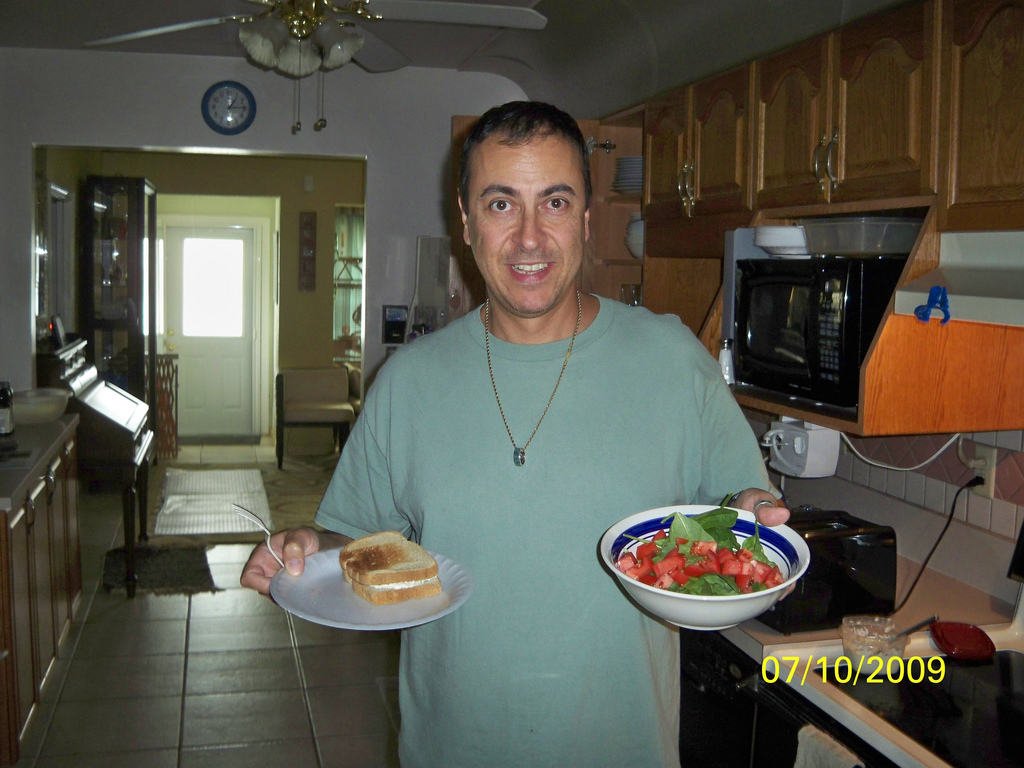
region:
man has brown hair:
[440, 109, 602, 224]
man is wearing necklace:
[469, 309, 583, 450]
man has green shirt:
[265, 331, 744, 762]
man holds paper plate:
[247, 533, 503, 682]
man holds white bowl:
[594, 485, 798, 635]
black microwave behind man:
[703, 214, 915, 436]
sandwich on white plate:
[291, 558, 478, 619]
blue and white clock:
[210, 78, 258, 118]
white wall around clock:
[159, 72, 319, 140]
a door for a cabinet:
[626, 103, 684, 190]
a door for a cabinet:
[751, 51, 819, 197]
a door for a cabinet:
[845, 22, 925, 197]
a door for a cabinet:
[934, 13, 1015, 204]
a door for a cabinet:
[0, 519, 48, 717]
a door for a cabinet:
[25, 468, 61, 700]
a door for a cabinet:
[39, 446, 79, 659]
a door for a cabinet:
[59, 440, 101, 625]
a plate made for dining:
[265, 519, 469, 650]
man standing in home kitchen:
[239, 97, 791, 766]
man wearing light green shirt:
[236, 102, 793, 766]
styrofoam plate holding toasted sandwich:
[266, 530, 472, 629]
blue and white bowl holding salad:
[598, 502, 813, 632]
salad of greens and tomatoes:
[615, 506, 786, 596]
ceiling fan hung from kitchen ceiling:
[86, 0, 552, 138]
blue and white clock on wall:
[198, 76, 260, 134]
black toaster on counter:
[751, 505, 900, 638]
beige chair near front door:
[273, 361, 360, 472]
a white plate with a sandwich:
[264, 527, 462, 638]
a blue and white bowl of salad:
[592, 496, 815, 632]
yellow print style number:
[760, 656, 783, 686]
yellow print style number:
[774, 652, 803, 690]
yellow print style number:
[816, 650, 830, 693]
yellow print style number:
[888, 650, 907, 686]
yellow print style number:
[905, 644, 929, 692]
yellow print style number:
[923, 647, 947, 693]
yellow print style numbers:
[758, 649, 803, 692]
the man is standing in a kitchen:
[239, 99, 812, 766]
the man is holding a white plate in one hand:
[268, 532, 474, 640]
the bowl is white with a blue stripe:
[593, 504, 815, 638]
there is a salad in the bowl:
[612, 504, 787, 603]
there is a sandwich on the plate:
[340, 531, 443, 605]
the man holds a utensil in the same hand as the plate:
[238, 504, 290, 561]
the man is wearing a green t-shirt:
[315, 295, 775, 766]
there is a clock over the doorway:
[195, 80, 260, 132]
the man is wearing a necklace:
[481, 291, 586, 465]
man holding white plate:
[230, 103, 809, 764]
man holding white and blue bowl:
[238, 103, 808, 761]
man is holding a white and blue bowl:
[239, 100, 816, 767]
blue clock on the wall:
[0, 47, 535, 424]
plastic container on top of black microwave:
[729, 208, 927, 421]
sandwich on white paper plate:
[274, 531, 480, 640]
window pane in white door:
[160, 221, 258, 437]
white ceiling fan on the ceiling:
[0, 0, 552, 141]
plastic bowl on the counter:
[2, 384, 80, 525]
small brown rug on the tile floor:
[31, 442, 401, 766]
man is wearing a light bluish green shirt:
[240, 95, 794, 766]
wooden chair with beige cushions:
[271, 363, 358, 471]